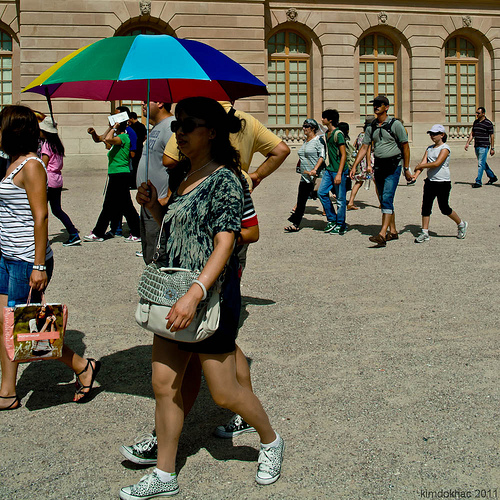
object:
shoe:
[120, 432, 171, 470]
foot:
[115, 430, 159, 465]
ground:
[0, 159, 500, 498]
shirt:
[151, 166, 247, 325]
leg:
[149, 329, 194, 470]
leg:
[416, 182, 438, 232]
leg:
[193, 313, 275, 446]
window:
[467, 63, 480, 75]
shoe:
[252, 433, 286, 486]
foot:
[255, 433, 284, 487]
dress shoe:
[70, 355, 97, 404]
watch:
[30, 263, 50, 275]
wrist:
[32, 262, 45, 271]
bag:
[0, 275, 70, 365]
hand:
[28, 265, 52, 292]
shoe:
[83, 232, 108, 246]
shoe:
[62, 233, 80, 242]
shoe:
[367, 230, 386, 245]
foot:
[368, 232, 388, 245]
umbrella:
[15, 32, 271, 204]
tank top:
[0, 155, 57, 265]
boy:
[317, 106, 351, 234]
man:
[314, 105, 351, 234]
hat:
[364, 95, 389, 106]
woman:
[0, 103, 102, 416]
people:
[462, 106, 500, 192]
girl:
[409, 121, 468, 245]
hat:
[427, 120, 452, 141]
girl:
[118, 95, 285, 498]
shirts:
[231, 163, 259, 286]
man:
[349, 91, 416, 248]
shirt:
[358, 114, 406, 163]